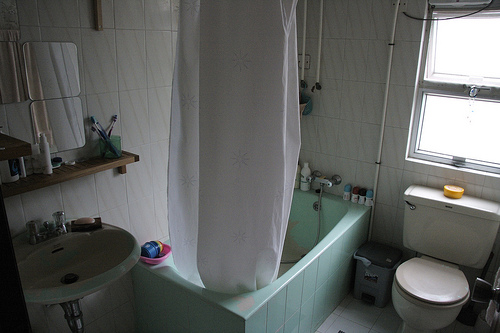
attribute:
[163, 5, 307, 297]
shower curtain — white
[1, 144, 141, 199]
shelf — wooden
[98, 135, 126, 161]
glass — green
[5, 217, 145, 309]
sink — oval